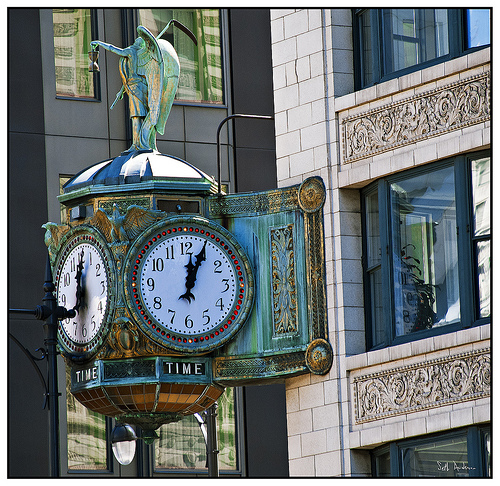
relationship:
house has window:
[243, 18, 479, 479] [352, 144, 481, 349]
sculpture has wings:
[60, 24, 225, 179] [131, 34, 210, 121]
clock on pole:
[43, 224, 118, 363] [119, 377, 170, 471]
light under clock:
[104, 410, 141, 453] [43, 224, 118, 363]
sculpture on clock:
[85, 19, 194, 156] [43, 224, 118, 363]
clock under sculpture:
[43, 224, 118, 363] [85, 19, 194, 156]